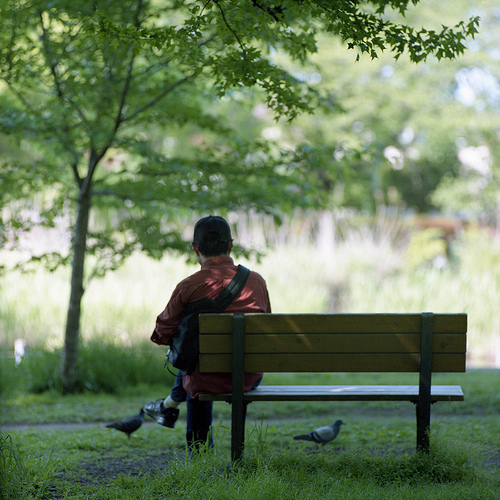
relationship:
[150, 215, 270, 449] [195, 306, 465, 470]
man sitting on bench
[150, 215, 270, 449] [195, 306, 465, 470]
man on bench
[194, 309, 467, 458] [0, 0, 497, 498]
bench in park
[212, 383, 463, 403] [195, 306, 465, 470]
seat of bench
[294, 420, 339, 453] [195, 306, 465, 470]
bird under bench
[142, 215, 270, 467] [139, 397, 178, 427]
man has foot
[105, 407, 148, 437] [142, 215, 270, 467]
bird near man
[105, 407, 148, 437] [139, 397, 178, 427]
bird near foot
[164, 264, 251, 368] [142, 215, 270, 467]
bag on man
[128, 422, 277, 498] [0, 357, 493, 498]
grass on ground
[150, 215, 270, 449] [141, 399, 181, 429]
man has shoe